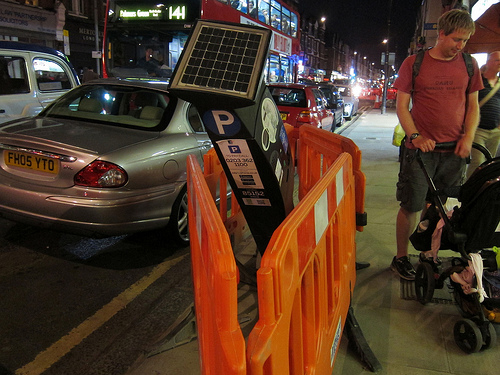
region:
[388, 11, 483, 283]
the man holding onto the stroller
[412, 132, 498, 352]
the stroller in front of the man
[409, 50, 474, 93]
the backpack straps around the man's shoulders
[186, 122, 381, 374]
the orange barricades around the parking meter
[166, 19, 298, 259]
the broken parking meter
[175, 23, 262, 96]
the solar panel on the parking meter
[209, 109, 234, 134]
the P on the parking meter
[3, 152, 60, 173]
the yellow license plate on the car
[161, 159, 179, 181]
the cover to the gas tank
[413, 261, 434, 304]
the wheel on the stroller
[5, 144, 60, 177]
a yellow license plate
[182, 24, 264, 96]
a solar panel on a parking meter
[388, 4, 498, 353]
a man pushing a stroller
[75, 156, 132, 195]
a red tail light in a silver car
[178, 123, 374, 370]
orange safety fence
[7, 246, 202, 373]
a yellow line on the street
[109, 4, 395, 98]
lights from storefronts along a street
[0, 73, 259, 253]
A silver car on the street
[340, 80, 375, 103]
lights shining in the distance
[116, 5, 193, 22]
a black and white advertisement sign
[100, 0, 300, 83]
a red double decker bus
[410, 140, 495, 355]
stroller pushed by the man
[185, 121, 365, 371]
a group of orange safety barriers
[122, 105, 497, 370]
a sidewalk in the city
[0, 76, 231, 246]
a car in the road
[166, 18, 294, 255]
a knocked over parking meter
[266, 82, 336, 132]
a red car in the road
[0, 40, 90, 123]
a car in the road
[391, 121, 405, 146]
a yellow shopping bag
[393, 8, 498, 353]
a man pushing a baby carriage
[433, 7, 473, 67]
a man with blonde hair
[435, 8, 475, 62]
the head of a man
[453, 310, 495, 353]
the wheels of a baby carriage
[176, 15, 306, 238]
a broken parking meter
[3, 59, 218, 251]
a silver car on the side of the street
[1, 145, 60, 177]
a yellow car license plate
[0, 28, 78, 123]
a white car on the street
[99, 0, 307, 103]
a red city bus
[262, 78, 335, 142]
a car parked on the side of the road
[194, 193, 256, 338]
orange barrier on sidewalk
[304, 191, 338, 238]
white square on orange barrier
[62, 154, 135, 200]
red and white lights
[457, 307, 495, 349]
double wheels on baby carraige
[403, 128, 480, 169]
man's hand on carraige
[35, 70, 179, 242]
old fashioned silver car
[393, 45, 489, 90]
black straps around man's shoulders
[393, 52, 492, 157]
red shirt with sleeves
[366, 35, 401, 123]
silver sign on side walk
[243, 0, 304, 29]
passenger in top of bus